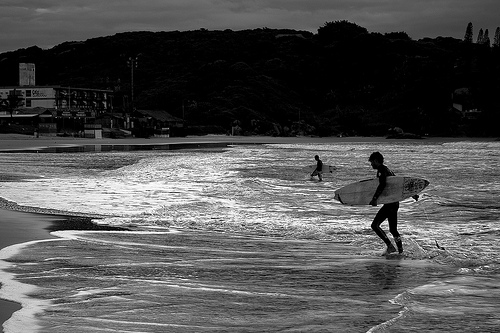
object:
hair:
[367, 151, 384, 164]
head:
[368, 151, 385, 170]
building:
[0, 62, 172, 138]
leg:
[386, 206, 401, 245]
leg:
[368, 207, 390, 244]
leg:
[317, 173, 322, 180]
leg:
[311, 172, 318, 178]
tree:
[1, 90, 22, 125]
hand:
[369, 198, 378, 207]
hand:
[412, 194, 419, 201]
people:
[310, 155, 324, 182]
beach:
[0, 134, 499, 333]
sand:
[0, 211, 49, 241]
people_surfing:
[332, 175, 430, 205]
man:
[368, 150, 419, 256]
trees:
[100, 2, 475, 157]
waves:
[90, 200, 355, 243]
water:
[0, 134, 499, 332]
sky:
[1, 2, 499, 49]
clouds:
[0, 0, 497, 51]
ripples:
[0, 142, 499, 332]